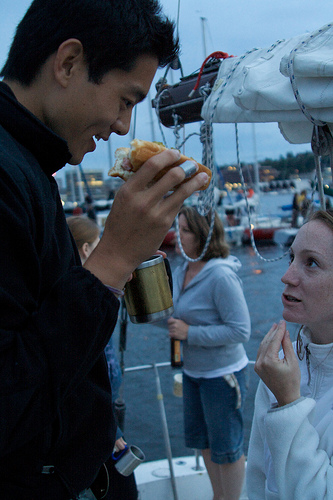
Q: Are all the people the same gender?
A: No, they are both male and female.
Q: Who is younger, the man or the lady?
A: The lady is younger than the man.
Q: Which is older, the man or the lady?
A: The man is older than the lady.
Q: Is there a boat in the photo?
A: Yes, there is a boat.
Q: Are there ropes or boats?
A: Yes, there is a boat.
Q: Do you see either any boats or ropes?
A: Yes, there is a boat.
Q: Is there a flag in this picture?
A: No, there are no flags.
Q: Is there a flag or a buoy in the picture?
A: No, there are no flags or buoys.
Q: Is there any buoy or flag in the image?
A: No, there are no flags or buoys.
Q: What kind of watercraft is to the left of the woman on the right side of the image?
A: The watercraft is a boat.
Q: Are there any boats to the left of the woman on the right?
A: Yes, there is a boat to the left of the woman.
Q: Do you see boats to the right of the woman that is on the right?
A: No, the boat is to the left of the woman.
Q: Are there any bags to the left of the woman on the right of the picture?
A: No, there is a boat to the left of the woman.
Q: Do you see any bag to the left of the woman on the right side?
A: No, there is a boat to the left of the woman.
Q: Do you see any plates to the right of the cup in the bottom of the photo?
A: No, there is a boat to the right of the cup.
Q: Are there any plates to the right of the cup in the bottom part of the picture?
A: No, there is a boat to the right of the cup.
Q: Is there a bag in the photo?
A: No, there are no bags.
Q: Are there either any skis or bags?
A: No, there are no bags or skis.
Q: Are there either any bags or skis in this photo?
A: No, there are no bags or skis.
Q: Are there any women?
A: Yes, there is a woman.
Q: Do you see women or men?
A: Yes, there is a woman.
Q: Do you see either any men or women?
A: Yes, there is a woman.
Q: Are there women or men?
A: Yes, there is a woman.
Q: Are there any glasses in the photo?
A: No, there are no glasses.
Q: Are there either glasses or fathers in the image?
A: No, there are no glasses or fathers.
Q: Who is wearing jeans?
A: The woman is wearing jeans.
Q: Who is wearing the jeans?
A: The woman is wearing jeans.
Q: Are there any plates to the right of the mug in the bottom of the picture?
A: No, there is a woman to the right of the mug.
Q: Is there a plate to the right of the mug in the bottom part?
A: No, there is a woman to the right of the mug.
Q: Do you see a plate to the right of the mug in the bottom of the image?
A: No, there is a woman to the right of the mug.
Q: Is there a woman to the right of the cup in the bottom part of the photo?
A: Yes, there is a woman to the right of the cup.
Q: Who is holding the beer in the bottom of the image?
A: The woman is holding the beer.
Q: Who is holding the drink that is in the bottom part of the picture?
A: The woman is holding the beer.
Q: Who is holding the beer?
A: The woman is holding the beer.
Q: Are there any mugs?
A: Yes, there is a mug.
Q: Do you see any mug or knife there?
A: Yes, there is a mug.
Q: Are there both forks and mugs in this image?
A: No, there is a mug but no forks.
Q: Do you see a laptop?
A: No, there are no laptops.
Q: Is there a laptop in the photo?
A: No, there are no laptops.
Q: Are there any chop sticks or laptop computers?
A: No, there are no laptop computers or chop sticks.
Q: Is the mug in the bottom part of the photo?
A: Yes, the mug is in the bottom of the image.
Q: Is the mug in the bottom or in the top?
A: The mug is in the bottom of the image.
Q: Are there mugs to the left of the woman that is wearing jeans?
A: Yes, there is a mug to the left of the woman.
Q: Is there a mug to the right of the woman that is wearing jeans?
A: No, the mug is to the left of the woman.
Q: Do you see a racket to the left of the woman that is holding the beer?
A: No, there is a mug to the left of the woman.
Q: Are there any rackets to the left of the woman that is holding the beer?
A: No, there is a mug to the left of the woman.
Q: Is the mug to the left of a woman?
A: Yes, the mug is to the left of a woman.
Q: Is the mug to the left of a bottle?
A: No, the mug is to the left of a woman.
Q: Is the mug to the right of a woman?
A: No, the mug is to the left of a woman.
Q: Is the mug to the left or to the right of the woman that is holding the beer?
A: The mug is to the left of the woman.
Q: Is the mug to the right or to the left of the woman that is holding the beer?
A: The mug is to the left of the woman.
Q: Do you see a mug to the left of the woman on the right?
A: Yes, there is a mug to the left of the woman.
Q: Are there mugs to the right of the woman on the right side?
A: No, the mug is to the left of the woman.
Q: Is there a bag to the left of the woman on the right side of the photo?
A: No, there is a mug to the left of the woman.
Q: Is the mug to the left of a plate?
A: No, the mug is to the left of the woman.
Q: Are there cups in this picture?
A: Yes, there is a cup.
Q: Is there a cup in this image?
A: Yes, there is a cup.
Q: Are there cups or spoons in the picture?
A: Yes, there is a cup.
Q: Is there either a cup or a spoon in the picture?
A: Yes, there is a cup.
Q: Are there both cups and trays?
A: No, there is a cup but no trays.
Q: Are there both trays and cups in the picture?
A: No, there is a cup but no trays.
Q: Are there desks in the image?
A: No, there are no desks.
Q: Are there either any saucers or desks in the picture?
A: No, there are no desks or saucers.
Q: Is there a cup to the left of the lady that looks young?
A: Yes, there is a cup to the left of the lady.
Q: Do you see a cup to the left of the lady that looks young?
A: Yes, there is a cup to the left of the lady.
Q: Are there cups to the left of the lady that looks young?
A: Yes, there is a cup to the left of the lady.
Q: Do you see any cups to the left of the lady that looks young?
A: Yes, there is a cup to the left of the lady.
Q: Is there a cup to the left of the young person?
A: Yes, there is a cup to the left of the lady.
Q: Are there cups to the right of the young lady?
A: No, the cup is to the left of the lady.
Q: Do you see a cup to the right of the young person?
A: No, the cup is to the left of the lady.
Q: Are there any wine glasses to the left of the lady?
A: No, there is a cup to the left of the lady.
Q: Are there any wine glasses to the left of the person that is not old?
A: No, there is a cup to the left of the lady.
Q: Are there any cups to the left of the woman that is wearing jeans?
A: Yes, there is a cup to the left of the woman.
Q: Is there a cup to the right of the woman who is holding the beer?
A: No, the cup is to the left of the woman.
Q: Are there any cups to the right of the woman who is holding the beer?
A: No, the cup is to the left of the woman.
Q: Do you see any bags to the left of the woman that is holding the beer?
A: No, there is a cup to the left of the woman.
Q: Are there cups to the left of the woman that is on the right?
A: Yes, there is a cup to the left of the woman.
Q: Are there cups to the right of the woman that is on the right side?
A: No, the cup is to the left of the woman.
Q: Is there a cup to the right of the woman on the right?
A: No, the cup is to the left of the woman.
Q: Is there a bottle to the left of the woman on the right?
A: No, there is a cup to the left of the woman.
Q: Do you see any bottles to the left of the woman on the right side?
A: No, there is a cup to the left of the woman.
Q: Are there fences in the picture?
A: No, there are no fences.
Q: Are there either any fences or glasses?
A: No, there are no fences or glasses.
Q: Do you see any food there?
A: Yes, there is food.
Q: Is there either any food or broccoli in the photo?
A: Yes, there is food.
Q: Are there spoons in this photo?
A: No, there are no spoons.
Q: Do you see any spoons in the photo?
A: No, there are no spoons.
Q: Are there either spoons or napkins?
A: No, there are no spoons or napkins.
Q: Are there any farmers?
A: No, there are no farmers.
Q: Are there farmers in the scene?
A: No, there are no farmers.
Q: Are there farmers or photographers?
A: No, there are no farmers or photographers.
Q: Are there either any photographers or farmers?
A: No, there are no farmers or photographers.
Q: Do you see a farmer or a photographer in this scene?
A: No, there are no farmers or photographers.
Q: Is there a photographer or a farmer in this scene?
A: No, there are no farmers or photographers.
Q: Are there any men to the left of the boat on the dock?
A: Yes, there is a man to the left of the boat.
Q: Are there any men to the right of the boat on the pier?
A: No, the man is to the left of the boat.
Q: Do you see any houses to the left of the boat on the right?
A: No, there is a man to the left of the boat.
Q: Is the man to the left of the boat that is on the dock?
A: Yes, the man is to the left of the boat.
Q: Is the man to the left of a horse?
A: No, the man is to the left of the boat.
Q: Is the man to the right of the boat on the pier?
A: No, the man is to the left of the boat.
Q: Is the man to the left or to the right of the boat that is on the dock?
A: The man is to the left of the boat.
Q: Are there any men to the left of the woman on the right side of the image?
A: Yes, there is a man to the left of the woman.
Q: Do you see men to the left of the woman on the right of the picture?
A: Yes, there is a man to the left of the woman.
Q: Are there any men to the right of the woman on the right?
A: No, the man is to the left of the woman.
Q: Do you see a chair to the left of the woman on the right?
A: No, there is a man to the left of the woman.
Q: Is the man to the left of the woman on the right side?
A: Yes, the man is to the left of the woman.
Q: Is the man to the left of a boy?
A: No, the man is to the left of the woman.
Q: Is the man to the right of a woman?
A: No, the man is to the left of a woman.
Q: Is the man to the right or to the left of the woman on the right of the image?
A: The man is to the left of the woman.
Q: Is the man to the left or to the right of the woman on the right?
A: The man is to the left of the woman.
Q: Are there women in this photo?
A: Yes, there is a woman.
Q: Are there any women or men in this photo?
A: Yes, there is a woman.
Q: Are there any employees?
A: No, there are no employees.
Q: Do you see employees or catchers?
A: No, there are no employees or catchers.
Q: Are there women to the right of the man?
A: Yes, there is a woman to the right of the man.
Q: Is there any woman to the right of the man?
A: Yes, there is a woman to the right of the man.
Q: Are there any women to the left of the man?
A: No, the woman is to the right of the man.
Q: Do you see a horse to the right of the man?
A: No, there is a woman to the right of the man.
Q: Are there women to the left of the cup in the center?
A: No, the woman is to the right of the cup.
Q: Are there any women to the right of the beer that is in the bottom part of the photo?
A: Yes, there is a woman to the right of the beer.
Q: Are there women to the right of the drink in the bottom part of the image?
A: Yes, there is a woman to the right of the beer.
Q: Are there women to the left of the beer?
A: No, the woman is to the right of the beer.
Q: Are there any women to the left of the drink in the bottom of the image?
A: No, the woman is to the right of the beer.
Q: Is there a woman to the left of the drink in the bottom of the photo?
A: No, the woman is to the right of the beer.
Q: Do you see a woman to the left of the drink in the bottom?
A: No, the woman is to the right of the beer.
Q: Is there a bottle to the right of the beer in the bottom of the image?
A: No, there is a woman to the right of the beer.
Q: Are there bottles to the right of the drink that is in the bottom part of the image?
A: No, there is a woman to the right of the beer.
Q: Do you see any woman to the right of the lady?
A: Yes, there is a woman to the right of the lady.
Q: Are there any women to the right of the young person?
A: Yes, there is a woman to the right of the lady.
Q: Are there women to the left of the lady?
A: No, the woman is to the right of the lady.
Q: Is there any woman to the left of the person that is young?
A: No, the woman is to the right of the lady.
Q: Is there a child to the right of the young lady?
A: No, there is a woman to the right of the lady.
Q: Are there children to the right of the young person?
A: No, there is a woman to the right of the lady.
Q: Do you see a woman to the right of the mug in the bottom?
A: Yes, there is a woman to the right of the mug.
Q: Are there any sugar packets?
A: No, there are no sugar packets.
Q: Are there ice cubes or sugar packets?
A: No, there are no sugar packets or ice cubes.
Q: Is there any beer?
A: Yes, there is beer.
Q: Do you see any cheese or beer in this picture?
A: Yes, there is beer.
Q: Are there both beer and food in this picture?
A: Yes, there are both beer and food.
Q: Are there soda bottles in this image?
A: No, there are no soda bottles.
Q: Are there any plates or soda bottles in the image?
A: No, there are no soda bottles or plates.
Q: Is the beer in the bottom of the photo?
A: Yes, the beer is in the bottom of the image.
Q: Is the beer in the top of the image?
A: No, the beer is in the bottom of the image.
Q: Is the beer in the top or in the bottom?
A: The beer is in the bottom of the image.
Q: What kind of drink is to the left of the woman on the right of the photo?
A: The drink is beer.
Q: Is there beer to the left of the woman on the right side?
A: Yes, there is beer to the left of the woman.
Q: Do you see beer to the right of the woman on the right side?
A: No, the beer is to the left of the woman.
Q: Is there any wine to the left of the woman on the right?
A: No, there is beer to the left of the woman.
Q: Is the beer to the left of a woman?
A: Yes, the beer is to the left of a woman.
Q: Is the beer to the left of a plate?
A: No, the beer is to the left of a woman.